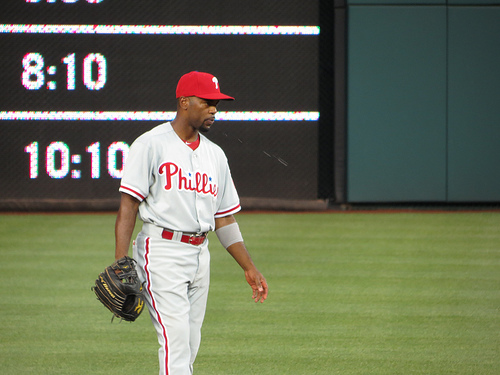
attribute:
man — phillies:
[115, 70, 269, 374]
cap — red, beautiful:
[176, 69, 236, 103]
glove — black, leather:
[89, 256, 145, 324]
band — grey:
[214, 220, 244, 250]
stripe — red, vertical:
[142, 233, 170, 374]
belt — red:
[159, 229, 207, 246]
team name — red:
[157, 160, 218, 196]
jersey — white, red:
[116, 120, 242, 236]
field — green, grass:
[1, 207, 499, 374]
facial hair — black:
[198, 114, 217, 132]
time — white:
[18, 47, 108, 92]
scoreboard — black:
[1, 1, 332, 202]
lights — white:
[0, 1, 320, 180]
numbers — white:
[17, 52, 130, 183]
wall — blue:
[345, 0, 499, 202]